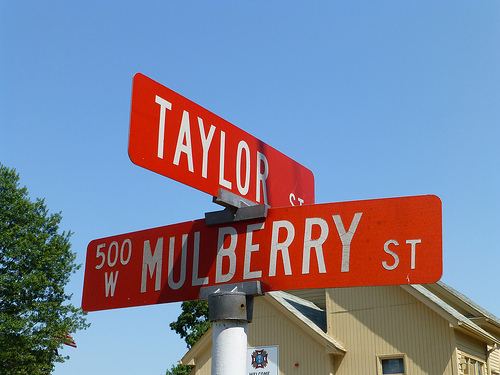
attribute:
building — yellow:
[232, 216, 493, 373]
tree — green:
[3, 157, 88, 368]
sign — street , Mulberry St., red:
[79, 194, 441, 313]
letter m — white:
[140, 238, 163, 293]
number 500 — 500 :
[85, 241, 140, 281]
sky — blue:
[0, 1, 499, 373]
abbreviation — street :
[382, 234, 424, 269]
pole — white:
[128, 152, 428, 372]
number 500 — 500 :
[88, 238, 134, 269]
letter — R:
[266, 218, 296, 278]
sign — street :
[70, 193, 443, 298]